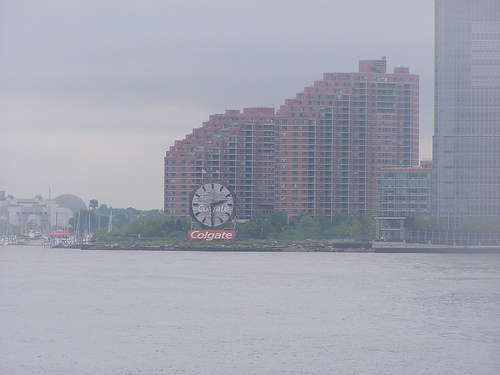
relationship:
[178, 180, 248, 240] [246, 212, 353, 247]
clock in grass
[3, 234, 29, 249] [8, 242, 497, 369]
boat floating on water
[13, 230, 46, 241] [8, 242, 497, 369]
boat floating on water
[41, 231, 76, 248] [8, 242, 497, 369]
boat floating on water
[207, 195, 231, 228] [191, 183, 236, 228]
hands on clock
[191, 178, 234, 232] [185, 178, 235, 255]
face on clock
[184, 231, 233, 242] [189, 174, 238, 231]
sign under clock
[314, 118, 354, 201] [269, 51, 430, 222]
windows on building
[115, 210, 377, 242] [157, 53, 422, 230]
trees in front of building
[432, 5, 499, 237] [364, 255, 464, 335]
skyscraper in front of water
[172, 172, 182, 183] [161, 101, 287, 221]
window on building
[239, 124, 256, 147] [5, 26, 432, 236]
window on building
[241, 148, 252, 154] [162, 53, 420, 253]
window on building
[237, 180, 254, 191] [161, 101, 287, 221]
window on building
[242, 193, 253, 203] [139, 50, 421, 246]
window on building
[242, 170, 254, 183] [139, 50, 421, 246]
window on building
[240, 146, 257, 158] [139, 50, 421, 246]
window on building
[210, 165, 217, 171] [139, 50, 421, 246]
window on building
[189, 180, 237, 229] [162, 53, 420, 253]
clock in front of building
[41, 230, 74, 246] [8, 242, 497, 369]
boat floating in water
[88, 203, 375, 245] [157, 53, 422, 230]
trees in front of building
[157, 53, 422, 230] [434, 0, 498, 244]
building beside building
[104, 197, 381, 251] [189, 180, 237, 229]
trees behind clock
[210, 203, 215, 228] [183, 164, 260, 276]
hands on a clock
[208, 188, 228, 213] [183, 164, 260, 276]
hour hand on a clock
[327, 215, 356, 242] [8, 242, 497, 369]
tree on side of water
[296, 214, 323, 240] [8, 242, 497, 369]
tree on side of water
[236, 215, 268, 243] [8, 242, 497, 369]
tree on side of water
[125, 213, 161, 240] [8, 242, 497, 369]
tree on side of water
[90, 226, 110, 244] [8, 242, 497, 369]
tree on side of water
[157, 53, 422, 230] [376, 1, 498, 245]
building next to building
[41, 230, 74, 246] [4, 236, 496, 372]
boat in harbor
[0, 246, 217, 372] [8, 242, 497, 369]
ripples in water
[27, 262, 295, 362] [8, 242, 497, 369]
ripples in water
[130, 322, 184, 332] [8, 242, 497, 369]
ripple in water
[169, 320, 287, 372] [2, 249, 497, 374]
ripples in water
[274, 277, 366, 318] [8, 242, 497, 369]
ripples in water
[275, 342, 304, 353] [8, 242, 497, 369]
ripples in water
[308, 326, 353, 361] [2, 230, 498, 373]
ripples in water